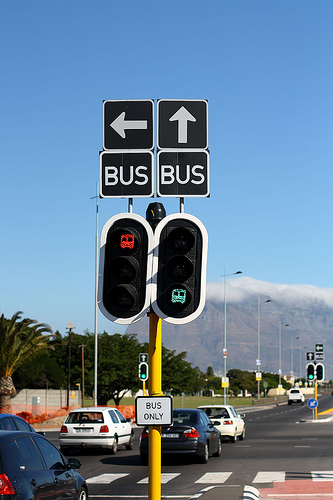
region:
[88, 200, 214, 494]
two traffic lights on a yellow pole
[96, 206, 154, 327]
traffic light has white border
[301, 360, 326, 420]
traffic lights have white borders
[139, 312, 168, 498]
the pole is color yellow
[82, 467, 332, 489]
white lines on the road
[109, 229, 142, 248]
picture of red bus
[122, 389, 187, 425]
white sign on yellow post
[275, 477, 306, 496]
pink paint on the street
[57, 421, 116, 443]
red lights on back of white car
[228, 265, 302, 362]
massive mountain range in the far distance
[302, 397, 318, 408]
white arrow sign on blue post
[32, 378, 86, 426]
tall gray wall on side of road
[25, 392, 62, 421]
orange netting in front of wall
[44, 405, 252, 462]
cars on the road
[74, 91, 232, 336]
these are street signs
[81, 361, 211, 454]
the cars are in traffic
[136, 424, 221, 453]
this car is black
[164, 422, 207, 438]
the tail light is red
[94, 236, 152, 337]
this light is red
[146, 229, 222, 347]
this light is green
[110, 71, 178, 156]
this is an arrow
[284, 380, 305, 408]
White jeep on the road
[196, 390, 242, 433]
white can on the highway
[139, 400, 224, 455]
blue car on the highway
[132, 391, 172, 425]
traffic sign showing bus only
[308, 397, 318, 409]
sign with a blue arrow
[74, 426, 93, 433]
license plate on the car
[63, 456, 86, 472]
mirror on the car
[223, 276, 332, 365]
mountain in the distance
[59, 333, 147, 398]
large tree near the curb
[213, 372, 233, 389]
yellow and white traffic sign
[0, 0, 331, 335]
clear blue of daytime sky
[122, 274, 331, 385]
hazy mountain on horizon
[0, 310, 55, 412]
green leaves of palm tree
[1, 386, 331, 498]
back of vehicles driving on street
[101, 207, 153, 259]
red signal on sign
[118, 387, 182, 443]
black and white sign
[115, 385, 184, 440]
sign with two words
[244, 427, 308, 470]
street next to cars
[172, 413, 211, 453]
back light on car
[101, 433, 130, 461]
back tire of car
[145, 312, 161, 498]
metal post by the black road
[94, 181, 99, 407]
metal post by the black road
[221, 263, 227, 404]
metal post by the black road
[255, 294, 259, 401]
metal post by the black road